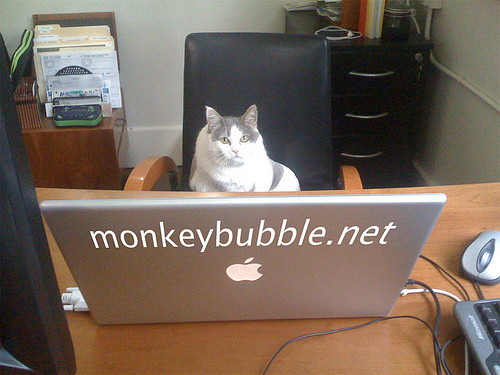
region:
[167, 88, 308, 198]
a grey and white cat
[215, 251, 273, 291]
the official apple logo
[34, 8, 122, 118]
a stack of envolopes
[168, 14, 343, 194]
a cat sitting on a chair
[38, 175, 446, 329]
the back of an open laptop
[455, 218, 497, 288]
a computer mouse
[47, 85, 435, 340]
a cat in front of a laptop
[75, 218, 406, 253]
a line of text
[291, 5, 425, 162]
a drawer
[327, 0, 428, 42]
a group of books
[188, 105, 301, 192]
the fat white and gray cat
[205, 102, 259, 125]
the cats pointy ears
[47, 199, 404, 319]
the cover of the macbook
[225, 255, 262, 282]
the lit up apple logo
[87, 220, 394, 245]
the website on the macbook cover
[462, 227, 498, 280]
the black and gray mouse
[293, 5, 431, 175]
the file cabinet in the back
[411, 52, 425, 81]
the key lock on the file cabinet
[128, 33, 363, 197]
the black computer chair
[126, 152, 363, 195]
the computer chair arm rests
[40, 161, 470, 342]
large mac laptop with a apple on it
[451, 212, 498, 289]
silver mouse with electric wires on it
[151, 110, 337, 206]
beautiful white and gray cat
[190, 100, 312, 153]
two big cat eyes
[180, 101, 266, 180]
several cat whiskers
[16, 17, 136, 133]
several business folders with papers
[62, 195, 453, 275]
laptop cover with the letter m on it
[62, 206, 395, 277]
laptop cover with the letter o on it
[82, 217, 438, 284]
laptop cover with the letter n on it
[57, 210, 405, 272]
laptop cover with the letter k on it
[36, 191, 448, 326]
a silver apple laptop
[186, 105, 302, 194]
a gray and white cat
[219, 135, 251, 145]
two green and black eyes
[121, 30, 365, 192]
black chair brown handles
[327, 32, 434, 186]
black metal file cabinet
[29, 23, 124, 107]
a group of yellow folders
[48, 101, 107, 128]
black and green hand held dvice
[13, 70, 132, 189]
brown wooden file cabinet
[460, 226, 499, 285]
black and white computer mouse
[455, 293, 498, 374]
black and gray keyboard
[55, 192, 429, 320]
opened lid of a laptop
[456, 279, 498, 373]
edge of a computer keyboard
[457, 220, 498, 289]
a wired mouse on a desk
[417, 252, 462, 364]
a bunch of wires on a desk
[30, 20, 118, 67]
a stack of manila folders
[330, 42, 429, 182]
a black filing cabinet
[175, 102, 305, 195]
a cat sitting in a chair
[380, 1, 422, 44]
a jar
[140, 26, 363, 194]
a black chair with wood handles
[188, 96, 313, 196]
a white and gray cat